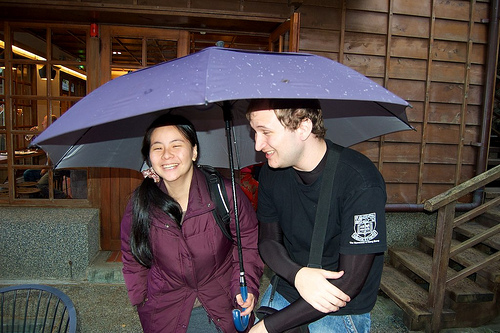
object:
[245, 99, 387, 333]
man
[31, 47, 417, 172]
umbrella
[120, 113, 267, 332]
woman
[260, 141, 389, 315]
shirt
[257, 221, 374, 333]
arm covers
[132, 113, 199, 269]
hair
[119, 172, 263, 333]
coat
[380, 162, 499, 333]
stairs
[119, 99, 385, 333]
couple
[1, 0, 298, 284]
shop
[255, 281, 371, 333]
pants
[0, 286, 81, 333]
seat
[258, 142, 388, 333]
sweater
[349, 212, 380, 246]
logo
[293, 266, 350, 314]
hand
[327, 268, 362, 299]
elbow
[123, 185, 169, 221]
shoulder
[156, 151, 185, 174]
smile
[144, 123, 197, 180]
face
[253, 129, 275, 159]
smile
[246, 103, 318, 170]
face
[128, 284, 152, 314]
hand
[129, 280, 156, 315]
pocket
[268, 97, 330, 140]
hair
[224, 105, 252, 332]
handle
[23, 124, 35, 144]
bottle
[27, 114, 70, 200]
man